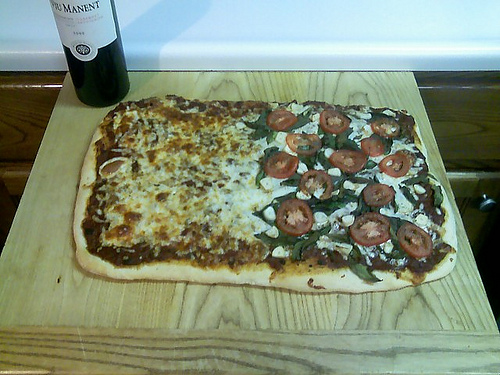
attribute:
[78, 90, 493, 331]
board — light brown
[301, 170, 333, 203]
tomato — sliced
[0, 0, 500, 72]
counter — white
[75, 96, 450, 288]
pizza — halved, rectangle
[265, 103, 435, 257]
nuts — white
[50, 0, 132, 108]
bottle — red, dark, glass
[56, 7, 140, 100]
wine bottle — dark 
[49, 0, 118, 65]
label — white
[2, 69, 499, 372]
board — wooden , tan 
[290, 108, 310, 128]
basil — green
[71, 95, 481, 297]
pizza — rectangle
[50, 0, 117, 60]
label — white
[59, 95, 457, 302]
pizza — square, cooked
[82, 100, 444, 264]
square pizza — sqaure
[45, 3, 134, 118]
wine — red 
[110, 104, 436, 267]
cheese — white 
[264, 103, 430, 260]
tomatoes — red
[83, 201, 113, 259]
sauce — red